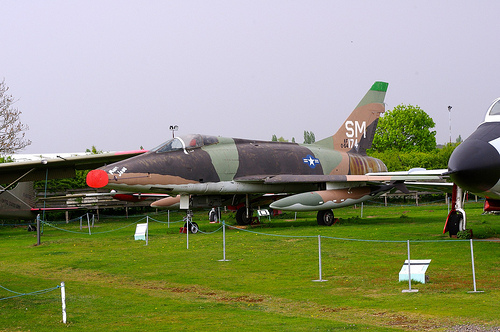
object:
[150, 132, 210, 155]
canopy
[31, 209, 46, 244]
pole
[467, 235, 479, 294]
pole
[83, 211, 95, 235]
pole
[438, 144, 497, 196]
nose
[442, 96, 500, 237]
aircraft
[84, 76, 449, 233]
plane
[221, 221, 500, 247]
line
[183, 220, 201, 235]
front wheel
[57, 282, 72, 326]
pole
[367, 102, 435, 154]
tree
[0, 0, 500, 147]
sky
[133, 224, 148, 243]
sign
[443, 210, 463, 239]
wheel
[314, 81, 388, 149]
tail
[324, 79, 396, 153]
rudder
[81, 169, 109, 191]
nose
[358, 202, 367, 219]
pole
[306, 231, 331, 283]
short pole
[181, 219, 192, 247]
pole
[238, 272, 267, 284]
patch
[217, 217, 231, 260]
pole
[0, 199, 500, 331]
grass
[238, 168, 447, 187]
wing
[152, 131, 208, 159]
cockpit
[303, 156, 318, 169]
circle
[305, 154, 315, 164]
star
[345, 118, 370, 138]
sm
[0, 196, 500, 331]
ground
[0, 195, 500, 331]
field